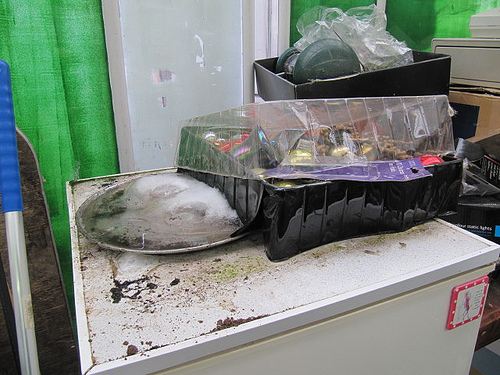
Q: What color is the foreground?
A: Green.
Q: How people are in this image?
A: None.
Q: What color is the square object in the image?
A: White.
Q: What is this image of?
A: Garbage.